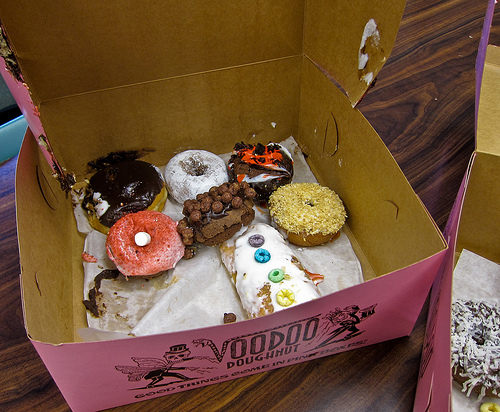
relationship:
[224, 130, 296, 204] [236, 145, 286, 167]
donut has orange frosting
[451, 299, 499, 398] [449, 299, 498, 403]
coconut on donut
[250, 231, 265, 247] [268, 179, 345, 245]
froot loop on donut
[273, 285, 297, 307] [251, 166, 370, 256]
froot loop on donut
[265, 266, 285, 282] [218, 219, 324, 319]
froot loop on donut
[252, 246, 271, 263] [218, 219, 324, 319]
froot loop on donut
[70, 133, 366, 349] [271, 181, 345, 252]
paper under donut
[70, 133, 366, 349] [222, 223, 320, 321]
paper under donut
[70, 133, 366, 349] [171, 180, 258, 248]
paper under donut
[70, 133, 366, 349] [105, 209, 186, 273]
paper under donut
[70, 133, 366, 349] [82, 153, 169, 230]
paper under donut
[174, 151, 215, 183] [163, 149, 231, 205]
ice on donut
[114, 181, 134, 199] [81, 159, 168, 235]
jam on donut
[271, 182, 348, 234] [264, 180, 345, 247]
icing on doughnut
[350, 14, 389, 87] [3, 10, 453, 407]
icing on box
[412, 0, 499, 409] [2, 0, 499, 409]
box on table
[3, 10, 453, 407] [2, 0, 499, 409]
box on table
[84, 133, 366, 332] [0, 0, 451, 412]
paper in box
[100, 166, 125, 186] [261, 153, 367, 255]
chocolate frosting donut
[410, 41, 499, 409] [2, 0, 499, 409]
box on table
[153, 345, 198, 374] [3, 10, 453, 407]
skull people on box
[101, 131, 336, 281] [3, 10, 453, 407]
snacks in box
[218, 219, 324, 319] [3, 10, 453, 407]
donut in box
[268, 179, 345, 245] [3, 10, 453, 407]
donut in box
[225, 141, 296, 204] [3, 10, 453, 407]
donut in box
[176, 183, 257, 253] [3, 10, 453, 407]
donut in box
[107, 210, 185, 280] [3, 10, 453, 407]
donut in box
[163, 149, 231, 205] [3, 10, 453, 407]
donut in box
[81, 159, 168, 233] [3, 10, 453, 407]
donut in box